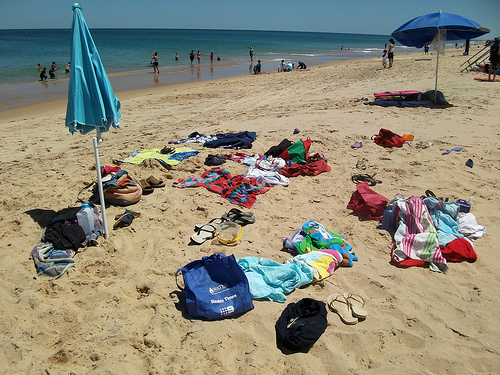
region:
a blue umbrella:
[62, 2, 124, 239]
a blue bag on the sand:
[171, 252, 255, 318]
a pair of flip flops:
[331, 289, 366, 324]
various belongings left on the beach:
[34, 129, 482, 355]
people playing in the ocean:
[31, 60, 76, 80]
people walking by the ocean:
[147, 42, 261, 71]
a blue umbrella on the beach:
[392, 12, 489, 107]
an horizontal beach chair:
[375, 88, 423, 100]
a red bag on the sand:
[348, 178, 387, 224]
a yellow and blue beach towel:
[120, 144, 197, 169]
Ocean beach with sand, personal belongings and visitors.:
[2, 2, 498, 374]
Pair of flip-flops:
[323, 290, 371, 328]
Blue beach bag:
[173, 252, 254, 322]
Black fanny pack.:
[274, 297, 329, 357]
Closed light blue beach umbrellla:
[64, 2, 124, 241]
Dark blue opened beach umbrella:
[388, 8, 490, 107]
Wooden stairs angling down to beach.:
[456, 42, 498, 73]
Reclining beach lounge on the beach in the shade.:
[368, 86, 434, 109]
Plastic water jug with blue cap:
[73, 200, 100, 238]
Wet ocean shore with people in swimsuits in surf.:
[0, 39, 317, 91]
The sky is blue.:
[0, 0, 499, 39]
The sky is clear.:
[1, 0, 499, 39]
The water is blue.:
[2, 28, 498, 83]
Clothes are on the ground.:
[33, 128, 485, 348]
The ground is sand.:
[3, 45, 499, 372]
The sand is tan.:
[2, 44, 499, 374]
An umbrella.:
[63, 1, 119, 241]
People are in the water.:
[32, 43, 265, 80]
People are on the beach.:
[376, 34, 433, 67]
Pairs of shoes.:
[187, 205, 254, 245]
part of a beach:
[263, 201, 279, 218]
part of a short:
[292, 328, 319, 360]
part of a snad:
[388, 293, 418, 332]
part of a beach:
[398, 285, 432, 320]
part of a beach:
[135, 310, 189, 368]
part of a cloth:
[246, 248, 282, 305]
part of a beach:
[358, 274, 378, 295]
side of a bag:
[189, 269, 201, 296]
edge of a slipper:
[348, 309, 352, 318]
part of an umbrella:
[66, 103, 106, 126]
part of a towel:
[401, 251, 435, 271]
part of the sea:
[113, 120, 132, 139]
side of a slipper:
[337, 303, 342, 309]